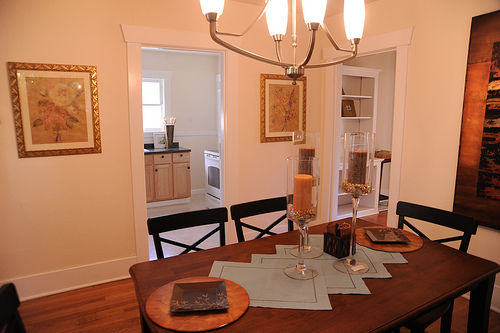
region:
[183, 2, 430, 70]
brown colored ceiling light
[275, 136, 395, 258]
clear champagne candle holders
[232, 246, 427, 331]
blue and brown placemats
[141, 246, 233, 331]
orange colored round plate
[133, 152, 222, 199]
brown and black cabinets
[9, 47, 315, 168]
gold framed artwork on wall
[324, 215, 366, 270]
brown box on table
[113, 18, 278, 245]
white framed wooden door frame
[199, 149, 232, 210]
white and black oven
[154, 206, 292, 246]
black wooden dining chair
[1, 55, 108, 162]
gold framed painting on wall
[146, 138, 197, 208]
black top wooden kitchen counter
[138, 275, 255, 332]
round wooden place mat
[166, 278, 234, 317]
square shaped plate with floral design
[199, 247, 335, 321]
grey square place mat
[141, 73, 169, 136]
window on top of kitchen counter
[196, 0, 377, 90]
four lamp chandelier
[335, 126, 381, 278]
tall glass candle holder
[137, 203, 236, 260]
black wooden chain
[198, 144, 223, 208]
white stove in kitchen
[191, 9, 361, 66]
the bulbs are four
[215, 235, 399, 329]
the table is brown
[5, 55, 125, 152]
painting is on the wall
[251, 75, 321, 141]
the painting is on the wall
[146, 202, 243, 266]
chairs are black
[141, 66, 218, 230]
the room is a kitchen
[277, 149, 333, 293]
the glass is cylindrical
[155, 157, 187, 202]
the cabinets are wooden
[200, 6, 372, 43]
the bulbs are cylindrical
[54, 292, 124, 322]
the floor is brown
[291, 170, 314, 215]
orange candle in a vase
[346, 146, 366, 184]
brown candle in a vase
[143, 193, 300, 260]
black chairs at the table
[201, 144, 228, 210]
white oven in the kitchen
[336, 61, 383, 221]
white bookcase in the other room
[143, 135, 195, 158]
black counter top in the kitchen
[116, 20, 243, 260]
thick white doorway frame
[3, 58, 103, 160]
picture hanging on the wall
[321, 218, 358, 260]
little brown basket on the table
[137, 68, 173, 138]
window in the kitchen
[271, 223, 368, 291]
three glass stems to three candle holders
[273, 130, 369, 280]
three clear glass candle holders on a wood table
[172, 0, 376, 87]
chandelier lamp over a dining table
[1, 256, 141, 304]
white baseboard along floor of a dining room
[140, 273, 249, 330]
round decorative brown pad on a dining table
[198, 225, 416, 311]
three gray place mats on a wooden dining table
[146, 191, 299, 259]
two black dining chairs next to a dining table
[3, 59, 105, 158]
framed art on the wall of a dining room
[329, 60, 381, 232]
built in white shelves in the room adjacent to the dining room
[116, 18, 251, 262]
white wooden door frame of door to the kitchen